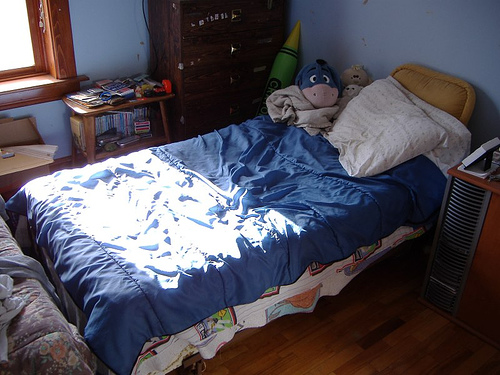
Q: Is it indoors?
A: Yes, it is indoors.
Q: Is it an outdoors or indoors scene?
A: It is indoors.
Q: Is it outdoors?
A: No, it is indoors.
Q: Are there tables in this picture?
A: Yes, there is a table.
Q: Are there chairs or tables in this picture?
A: Yes, there is a table.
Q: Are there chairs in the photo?
A: No, there are no chairs.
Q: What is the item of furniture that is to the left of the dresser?
A: The piece of furniture is a table.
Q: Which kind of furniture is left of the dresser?
A: The piece of furniture is a table.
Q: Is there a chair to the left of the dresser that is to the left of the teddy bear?
A: No, there is a table to the left of the dresser.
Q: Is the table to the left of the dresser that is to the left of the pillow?
A: Yes, the table is to the left of the dresser.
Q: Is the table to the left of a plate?
A: No, the table is to the left of the dresser.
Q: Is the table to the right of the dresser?
A: No, the table is to the left of the dresser.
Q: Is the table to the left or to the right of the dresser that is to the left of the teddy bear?
A: The table is to the left of the dresser.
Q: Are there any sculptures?
A: No, there are no sculptures.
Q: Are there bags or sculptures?
A: No, there are no sculptures or bags.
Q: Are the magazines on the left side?
A: Yes, the magazines are on the left of the image.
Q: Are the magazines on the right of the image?
A: No, the magazines are on the left of the image.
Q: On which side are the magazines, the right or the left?
A: The magazines are on the left of the image.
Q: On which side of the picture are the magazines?
A: The magazines are on the left of the image.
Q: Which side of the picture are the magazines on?
A: The magazines are on the left of the image.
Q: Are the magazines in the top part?
A: Yes, the magazines are in the top of the image.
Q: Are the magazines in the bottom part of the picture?
A: No, the magazines are in the top of the image.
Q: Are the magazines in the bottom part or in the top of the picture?
A: The magazines are in the top of the image.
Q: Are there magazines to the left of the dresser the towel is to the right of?
A: Yes, there are magazines to the left of the dresser.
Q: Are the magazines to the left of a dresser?
A: Yes, the magazines are to the left of a dresser.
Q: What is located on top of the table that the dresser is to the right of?
A: The magazines are on top of the table.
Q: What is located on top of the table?
A: The magazines are on top of the table.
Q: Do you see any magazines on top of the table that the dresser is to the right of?
A: Yes, there are magazines on top of the table.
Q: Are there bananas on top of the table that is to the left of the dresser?
A: No, there are magazines on top of the table.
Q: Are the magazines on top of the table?
A: Yes, the magazines are on top of the table.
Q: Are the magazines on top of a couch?
A: No, the magazines are on top of the table.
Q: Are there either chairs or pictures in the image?
A: No, there are no pictures or chairs.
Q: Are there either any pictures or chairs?
A: No, there are no pictures or chairs.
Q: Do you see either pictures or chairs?
A: No, there are no pictures or chairs.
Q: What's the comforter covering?
A: The comforter is covering the bed.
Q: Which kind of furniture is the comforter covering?
A: The comforter is covering the bed.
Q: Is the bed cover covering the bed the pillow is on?
A: Yes, the bed cover is covering the bed.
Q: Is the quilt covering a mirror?
A: No, the quilt is covering the bed.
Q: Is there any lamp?
A: No, there are no lamps.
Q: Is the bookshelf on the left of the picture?
A: Yes, the bookshelf is on the left of the image.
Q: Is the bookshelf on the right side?
A: No, the bookshelf is on the left of the image.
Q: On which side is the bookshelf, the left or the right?
A: The bookshelf is on the left of the image.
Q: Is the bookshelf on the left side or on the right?
A: The bookshelf is on the left of the image.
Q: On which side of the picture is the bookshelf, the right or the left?
A: The bookshelf is on the left of the image.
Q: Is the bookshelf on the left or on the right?
A: The bookshelf is on the left of the image.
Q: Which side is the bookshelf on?
A: The bookshelf is on the left of the image.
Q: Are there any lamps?
A: No, there are no lamps.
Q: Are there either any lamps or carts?
A: No, there are no lamps or carts.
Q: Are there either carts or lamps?
A: No, there are no lamps or carts.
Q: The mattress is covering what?
A: The mattress is covering the bed.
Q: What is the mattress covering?
A: The mattress is covering the bed.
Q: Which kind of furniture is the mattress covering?
A: The mattress is covering the bed.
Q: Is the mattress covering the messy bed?
A: Yes, the mattress is covering the bed.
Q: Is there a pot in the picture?
A: No, there are no pots.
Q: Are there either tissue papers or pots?
A: No, there are no pots or tissue papers.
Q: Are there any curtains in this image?
A: No, there are no curtains.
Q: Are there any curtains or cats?
A: No, there are no curtains or cats.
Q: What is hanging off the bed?
A: The sheet is hanging off the bed.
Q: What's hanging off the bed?
A: The sheet is hanging off the bed.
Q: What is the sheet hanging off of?
A: The sheet is hanging off the bed.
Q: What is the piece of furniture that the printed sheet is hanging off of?
A: The piece of furniture is a bed.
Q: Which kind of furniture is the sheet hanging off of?
A: The bed sheet is hanging off the bed.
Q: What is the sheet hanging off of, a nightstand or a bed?
A: The sheet is hanging off a bed.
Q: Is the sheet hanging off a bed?
A: Yes, the sheet is hanging off a bed.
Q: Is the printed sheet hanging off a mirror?
A: No, the bed sheet is hanging off a bed.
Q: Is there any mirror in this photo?
A: No, there are no mirrors.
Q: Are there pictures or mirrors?
A: No, there are no mirrors or pictures.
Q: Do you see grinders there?
A: No, there are no grinders.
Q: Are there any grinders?
A: No, there are no grinders.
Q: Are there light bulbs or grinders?
A: No, there are no grinders or light bulbs.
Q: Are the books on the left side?
A: Yes, the books are on the left of the image.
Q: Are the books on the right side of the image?
A: No, the books are on the left of the image.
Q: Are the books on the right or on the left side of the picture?
A: The books are on the left of the image.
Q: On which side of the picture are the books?
A: The books are on the left of the image.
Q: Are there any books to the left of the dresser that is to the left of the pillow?
A: Yes, there are books to the left of the dresser.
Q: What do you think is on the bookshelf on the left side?
A: The books are on the bookshelf.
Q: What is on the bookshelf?
A: The books are on the bookshelf.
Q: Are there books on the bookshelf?
A: Yes, there are books on the bookshelf.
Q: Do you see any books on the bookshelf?
A: Yes, there are books on the bookshelf.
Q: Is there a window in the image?
A: Yes, there is a window.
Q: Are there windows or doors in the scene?
A: Yes, there is a window.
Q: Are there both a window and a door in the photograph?
A: No, there is a window but no doors.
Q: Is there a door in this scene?
A: No, there are no doors.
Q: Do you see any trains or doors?
A: No, there are no doors or trains.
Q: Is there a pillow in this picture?
A: Yes, there is a pillow.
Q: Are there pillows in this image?
A: Yes, there is a pillow.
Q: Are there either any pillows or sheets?
A: Yes, there is a pillow.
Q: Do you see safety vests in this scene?
A: No, there are no safety vests.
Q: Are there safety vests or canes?
A: No, there are no safety vests or canes.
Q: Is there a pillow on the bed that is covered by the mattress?
A: Yes, there is a pillow on the bed.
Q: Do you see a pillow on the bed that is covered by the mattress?
A: Yes, there is a pillow on the bed.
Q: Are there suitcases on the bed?
A: No, there is a pillow on the bed.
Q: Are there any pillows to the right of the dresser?
A: Yes, there is a pillow to the right of the dresser.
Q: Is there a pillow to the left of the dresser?
A: No, the pillow is to the right of the dresser.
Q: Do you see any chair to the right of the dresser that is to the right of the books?
A: No, there is a pillow to the right of the dresser.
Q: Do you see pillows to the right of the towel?
A: Yes, there is a pillow to the right of the towel.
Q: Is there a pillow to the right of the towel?
A: Yes, there is a pillow to the right of the towel.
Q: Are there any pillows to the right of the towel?
A: Yes, there is a pillow to the right of the towel.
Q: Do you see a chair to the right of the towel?
A: No, there is a pillow to the right of the towel.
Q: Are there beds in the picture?
A: Yes, there is a bed.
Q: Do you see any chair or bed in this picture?
A: Yes, there is a bed.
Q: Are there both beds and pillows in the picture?
A: Yes, there are both a bed and pillows.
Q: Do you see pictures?
A: No, there are no pictures.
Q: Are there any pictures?
A: No, there are no pictures.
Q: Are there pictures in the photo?
A: No, there are no pictures.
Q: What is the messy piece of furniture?
A: The piece of furniture is a bed.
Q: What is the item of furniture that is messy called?
A: The piece of furniture is a bed.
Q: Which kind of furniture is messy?
A: The furniture is a bed.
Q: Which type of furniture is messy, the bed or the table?
A: The bed is messy.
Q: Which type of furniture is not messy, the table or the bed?
A: The table is not messy.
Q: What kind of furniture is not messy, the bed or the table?
A: The table is not messy.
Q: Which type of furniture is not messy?
A: The furniture is a table.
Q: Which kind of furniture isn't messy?
A: The furniture is a table.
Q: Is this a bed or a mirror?
A: This is a bed.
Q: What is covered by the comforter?
A: The bed is covered by the comforter.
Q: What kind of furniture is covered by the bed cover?
A: The piece of furniture is a bed.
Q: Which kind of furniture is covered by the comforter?
A: The piece of furniture is a bed.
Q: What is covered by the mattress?
A: The bed is covered by the mattress.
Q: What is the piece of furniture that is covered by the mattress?
A: The piece of furniture is a bed.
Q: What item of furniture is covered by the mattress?
A: The piece of furniture is a bed.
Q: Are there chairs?
A: No, there are no chairs.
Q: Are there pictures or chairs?
A: No, there are no chairs or pictures.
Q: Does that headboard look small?
A: Yes, the headboard is small.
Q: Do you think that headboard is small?
A: Yes, the headboard is small.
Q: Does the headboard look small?
A: Yes, the headboard is small.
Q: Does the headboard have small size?
A: Yes, the headboard is small.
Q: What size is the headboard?
A: The headboard is small.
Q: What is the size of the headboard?
A: The headboard is small.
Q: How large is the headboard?
A: The headboard is small.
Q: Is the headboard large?
A: No, the headboard is small.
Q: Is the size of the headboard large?
A: No, the headboard is small.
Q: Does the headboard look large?
A: No, the headboard is small.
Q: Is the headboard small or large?
A: The headboard is small.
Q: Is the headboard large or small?
A: The headboard is small.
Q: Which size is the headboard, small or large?
A: The headboard is small.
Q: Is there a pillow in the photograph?
A: Yes, there is a pillow.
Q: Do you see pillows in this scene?
A: Yes, there is a pillow.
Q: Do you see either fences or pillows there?
A: Yes, there is a pillow.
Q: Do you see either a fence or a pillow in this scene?
A: Yes, there is a pillow.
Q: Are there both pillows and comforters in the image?
A: Yes, there are both a pillow and a comforter.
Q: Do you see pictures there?
A: No, there are no pictures.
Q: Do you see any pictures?
A: No, there are no pictures.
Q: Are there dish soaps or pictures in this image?
A: No, there are no pictures or dish soaps.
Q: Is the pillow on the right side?
A: Yes, the pillow is on the right of the image.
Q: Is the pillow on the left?
A: No, the pillow is on the right of the image.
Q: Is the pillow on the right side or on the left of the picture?
A: The pillow is on the right of the image.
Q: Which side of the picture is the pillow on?
A: The pillow is on the right of the image.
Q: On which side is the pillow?
A: The pillow is on the right of the image.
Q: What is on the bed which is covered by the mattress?
A: The pillow is on the bed.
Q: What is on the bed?
A: The pillow is on the bed.